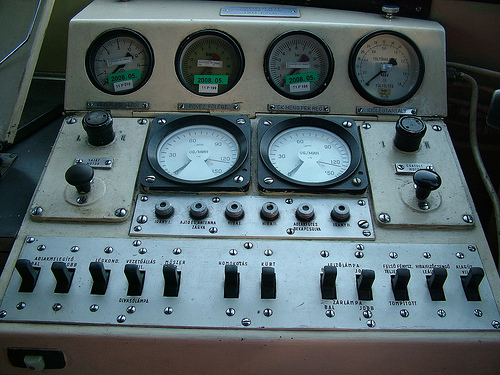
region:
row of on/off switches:
[5, 251, 499, 311]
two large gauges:
[155, 109, 361, 194]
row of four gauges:
[72, 23, 439, 107]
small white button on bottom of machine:
[6, 350, 67, 372]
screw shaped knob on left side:
[57, 161, 107, 198]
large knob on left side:
[80, 103, 123, 145]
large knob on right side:
[388, 115, 431, 151]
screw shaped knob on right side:
[405, 163, 455, 212]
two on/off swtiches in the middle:
[207, 252, 285, 309]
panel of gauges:
[13, 5, 499, 340]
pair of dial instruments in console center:
[151, 112, 368, 194]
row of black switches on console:
[13, 256, 493, 311]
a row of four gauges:
[83, 17, 436, 104]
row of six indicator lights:
[144, 198, 358, 225]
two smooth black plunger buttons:
[63, 159, 449, 211]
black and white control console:
[11, 1, 498, 356]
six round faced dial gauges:
[77, 21, 427, 203]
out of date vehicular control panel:
[8, 0, 499, 341]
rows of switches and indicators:
[3, 193, 498, 353]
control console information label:
[221, 0, 301, 17]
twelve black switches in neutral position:
[9, 246, 492, 313]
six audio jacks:
[137, 193, 372, 238]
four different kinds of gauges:
[75, 22, 445, 107]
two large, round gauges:
[145, 110, 368, 191]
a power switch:
[6, 332, 85, 374]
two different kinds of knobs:
[55, 105, 125, 219]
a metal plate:
[206, 0, 326, 27]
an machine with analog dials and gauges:
[12, 5, 474, 374]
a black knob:
[387, 158, 460, 219]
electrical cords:
[451, 59, 498, 137]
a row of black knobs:
[0, 241, 490, 311]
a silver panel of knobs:
[12, 230, 479, 330]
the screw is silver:
[235, 312, 257, 332]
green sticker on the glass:
[272, 64, 321, 85]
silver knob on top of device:
[362, 2, 407, 22]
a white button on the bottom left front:
[12, 347, 54, 369]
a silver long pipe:
[452, 61, 498, 228]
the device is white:
[33, 2, 464, 242]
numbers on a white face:
[152, 125, 232, 175]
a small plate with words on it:
[210, 0, 301, 25]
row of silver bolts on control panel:
[12, 305, 485, 333]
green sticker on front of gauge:
[188, 70, 242, 85]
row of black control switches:
[8, 257, 498, 304]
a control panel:
[7, 12, 499, 342]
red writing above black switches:
[28, 252, 186, 270]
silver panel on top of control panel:
[215, 2, 312, 18]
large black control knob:
[53, 99, 135, 159]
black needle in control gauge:
[357, 43, 414, 94]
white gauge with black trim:
[137, 110, 262, 194]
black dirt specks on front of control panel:
[210, 329, 315, 363]